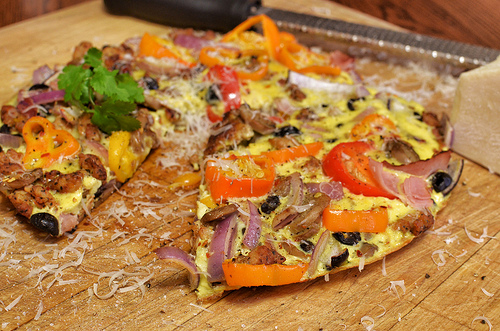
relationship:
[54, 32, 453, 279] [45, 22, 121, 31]
pizza on table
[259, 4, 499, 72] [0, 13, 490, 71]
grader in background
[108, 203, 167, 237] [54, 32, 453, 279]
cheese from pizza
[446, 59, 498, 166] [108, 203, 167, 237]
block of cheese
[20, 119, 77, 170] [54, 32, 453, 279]
pepper on pizza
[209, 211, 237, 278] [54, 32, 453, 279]
onion on pizza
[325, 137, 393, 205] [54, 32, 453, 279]
tomato on pizza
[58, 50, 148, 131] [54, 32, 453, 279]
parsley on pizza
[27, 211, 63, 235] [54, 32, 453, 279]
olives on pizza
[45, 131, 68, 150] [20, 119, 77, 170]
slice of pepper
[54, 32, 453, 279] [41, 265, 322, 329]
pizza on board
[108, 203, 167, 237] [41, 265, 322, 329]
cheese on board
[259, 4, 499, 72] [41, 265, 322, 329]
grader on board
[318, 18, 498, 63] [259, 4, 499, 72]
blade of knife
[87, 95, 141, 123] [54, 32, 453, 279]
lettuce on pizza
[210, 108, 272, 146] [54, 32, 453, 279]
chicken on pizza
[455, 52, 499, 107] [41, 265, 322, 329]
napkin on board